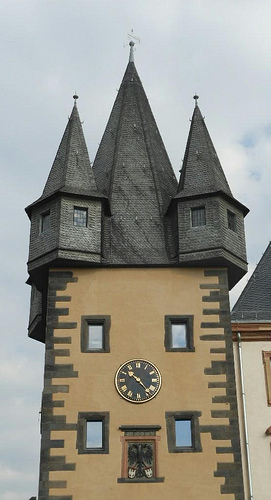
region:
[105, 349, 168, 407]
clock on side of building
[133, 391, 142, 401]
roman numeral on clock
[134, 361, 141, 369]
roman numeral on clock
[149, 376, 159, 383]
roman numeral on clock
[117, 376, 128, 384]
roman numeral on clock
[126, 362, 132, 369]
roman numeral on clock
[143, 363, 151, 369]
roman numeral on clock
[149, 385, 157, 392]
roman numeral on clock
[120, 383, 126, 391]
roman numeral on clock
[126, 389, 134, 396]
roman numeral on clock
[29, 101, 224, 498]
Picture taken during the day.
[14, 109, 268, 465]
Picture taken outdoors.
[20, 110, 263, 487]
A large building with a clock.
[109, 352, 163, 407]
The clock has roman numerals.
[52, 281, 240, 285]
The building is made of bricks.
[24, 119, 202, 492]
The bulding is very old.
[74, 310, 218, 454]
The building has four windows.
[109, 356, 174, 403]
The clock says 10:22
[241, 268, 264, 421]
A building is next to the other building.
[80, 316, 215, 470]
The sky reflects against the windows.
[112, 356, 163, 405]
Black and gold clock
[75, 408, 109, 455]
Black framed window on the side of building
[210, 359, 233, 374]
Dark colored bricks framing building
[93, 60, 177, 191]
Steeple top of building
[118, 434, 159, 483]
Emblem on side of building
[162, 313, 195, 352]
Top window of building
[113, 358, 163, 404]
Clocking showing that it is ten twenty three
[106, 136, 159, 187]
Dark grey roof tile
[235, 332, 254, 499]
Silver drain pipe on building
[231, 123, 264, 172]
Light blue sky with a lot of clouds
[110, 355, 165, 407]
a clock on a tower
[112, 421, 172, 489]
a symbol on the tower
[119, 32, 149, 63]
the top of the tower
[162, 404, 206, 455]
windows on a tower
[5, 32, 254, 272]
roof top of a tower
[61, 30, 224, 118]
three pecks on a tower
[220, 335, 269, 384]
white building next to tower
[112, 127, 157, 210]
wooden slate roof of tower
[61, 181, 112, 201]
roof edge of a tower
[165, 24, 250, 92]
clear skys over the tower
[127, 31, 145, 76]
the tip of the tallest spire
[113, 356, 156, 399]
the round clock face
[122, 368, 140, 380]
the hour hand on the clock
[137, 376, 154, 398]
the minute hand on the clock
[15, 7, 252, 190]
the sky behind the spires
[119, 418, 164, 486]
the door with the eagle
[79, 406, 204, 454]
the windows below the clock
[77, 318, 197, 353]
the windows above the clock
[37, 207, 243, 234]
the windows on the spires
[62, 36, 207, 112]
the tips of the three spires